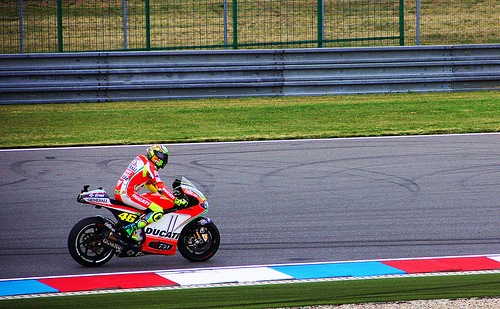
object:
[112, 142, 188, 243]
motorcyclist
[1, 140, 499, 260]
tire marks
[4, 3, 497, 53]
field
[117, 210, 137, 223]
number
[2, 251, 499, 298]
buffer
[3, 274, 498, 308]
infield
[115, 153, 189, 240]
clothing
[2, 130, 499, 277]
straightaway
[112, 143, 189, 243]
racer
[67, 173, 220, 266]
bike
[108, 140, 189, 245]
man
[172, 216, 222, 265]
front wheel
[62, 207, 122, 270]
rear wheel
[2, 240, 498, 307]
raceway side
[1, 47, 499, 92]
guardrail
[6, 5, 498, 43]
fence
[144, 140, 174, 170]
helmet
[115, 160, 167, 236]
outfit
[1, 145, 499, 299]
raceway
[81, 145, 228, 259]
motorcycle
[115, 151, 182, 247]
suit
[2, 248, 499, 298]
line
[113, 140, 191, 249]
driver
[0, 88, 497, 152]
grass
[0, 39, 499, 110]
wall